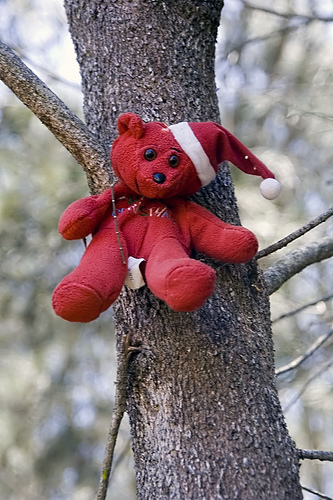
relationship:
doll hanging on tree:
[51, 112, 281, 323] [112, 261, 299, 498]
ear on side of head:
[114, 109, 143, 140] [107, 108, 204, 203]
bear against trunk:
[48, 108, 283, 322] [155, 366, 252, 444]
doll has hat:
[51, 112, 281, 323] [167, 121, 281, 201]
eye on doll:
[166, 154, 181, 166] [51, 112, 281, 323]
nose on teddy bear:
[151, 170, 166, 184] [49, 110, 257, 322]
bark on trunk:
[62, 36, 295, 492] [83, 26, 199, 85]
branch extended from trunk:
[0, 40, 109, 186] [62, 0, 304, 499]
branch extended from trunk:
[254, 206, 331, 259] [62, 0, 304, 499]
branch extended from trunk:
[293, 448, 332, 460] [62, 0, 304, 499]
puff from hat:
[258, 177, 286, 198] [167, 121, 281, 201]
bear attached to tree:
[48, 108, 283, 322] [1, 2, 330, 497]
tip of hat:
[253, 164, 284, 201] [165, 116, 282, 199]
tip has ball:
[253, 164, 284, 201] [259, 176, 281, 201]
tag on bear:
[121, 252, 147, 291] [48, 108, 283, 322]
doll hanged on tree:
[43, 95, 273, 298] [1, 2, 330, 497]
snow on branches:
[103, 456, 144, 497] [265, 236, 330, 294]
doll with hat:
[51, 112, 281, 323] [165, 116, 282, 199]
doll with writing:
[51, 112, 281, 323] [112, 196, 170, 221]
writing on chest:
[112, 196, 170, 221] [112, 194, 182, 234]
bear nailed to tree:
[52, 112, 281, 326] [81, 32, 285, 413]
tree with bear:
[57, 3, 293, 287] [57, 114, 267, 324]